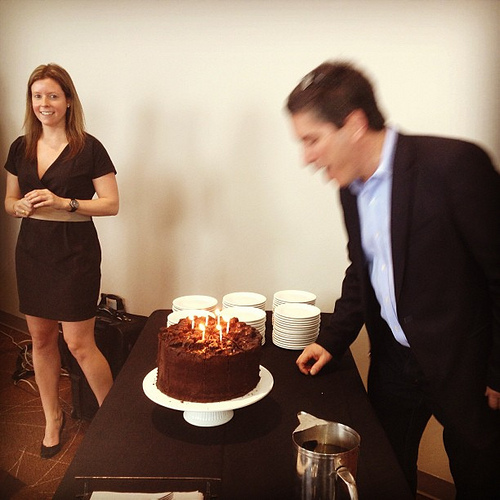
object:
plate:
[271, 301, 323, 319]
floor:
[0, 322, 93, 500]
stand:
[180, 412, 233, 426]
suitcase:
[70, 293, 150, 421]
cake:
[156, 315, 261, 400]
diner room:
[0, 0, 499, 500]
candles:
[220, 326, 222, 340]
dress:
[1, 130, 118, 321]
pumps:
[39, 412, 66, 458]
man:
[285, 61, 500, 500]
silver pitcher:
[291, 420, 365, 499]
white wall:
[0, 0, 499, 484]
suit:
[310, 129, 499, 428]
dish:
[141, 363, 275, 428]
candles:
[200, 322, 208, 340]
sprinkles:
[158, 318, 261, 358]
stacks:
[271, 311, 323, 351]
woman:
[3, 65, 118, 460]